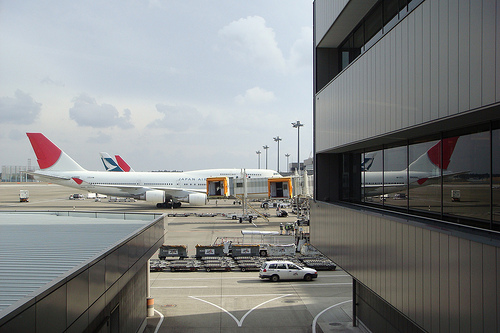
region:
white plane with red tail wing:
[22, 123, 293, 218]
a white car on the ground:
[248, 255, 323, 291]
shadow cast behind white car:
[238, 267, 273, 289]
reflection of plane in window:
[350, 148, 498, 215]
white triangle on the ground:
[187, 278, 307, 330]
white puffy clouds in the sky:
[19, 23, 294, 148]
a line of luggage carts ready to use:
[152, 242, 347, 284]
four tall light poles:
[237, 120, 314, 190]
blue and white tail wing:
[99, 146, 130, 182]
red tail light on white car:
[263, 263, 269, 273]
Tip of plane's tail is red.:
[18, 127, 63, 169]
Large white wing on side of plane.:
[66, 171, 217, 223]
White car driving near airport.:
[248, 240, 330, 321]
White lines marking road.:
[186, 270, 295, 330]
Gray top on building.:
[18, 248, 145, 318]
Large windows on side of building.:
[333, 131, 488, 193]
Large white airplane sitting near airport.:
[45, 152, 268, 207]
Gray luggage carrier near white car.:
[162, 238, 313, 258]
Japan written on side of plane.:
[169, 175, 199, 188]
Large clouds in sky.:
[72, 43, 261, 135]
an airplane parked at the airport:
[24, 130, 300, 212]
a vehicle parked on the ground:
[254, 253, 322, 286]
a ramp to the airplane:
[207, 176, 319, 204]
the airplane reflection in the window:
[349, 135, 458, 194]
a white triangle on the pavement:
[187, 288, 299, 331]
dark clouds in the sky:
[0, 3, 325, 174]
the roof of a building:
[0, 203, 170, 324]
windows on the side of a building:
[314, 112, 499, 237]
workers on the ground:
[273, 216, 299, 237]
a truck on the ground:
[13, 184, 35, 205]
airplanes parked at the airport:
[23, 28, 408, 314]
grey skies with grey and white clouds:
[57, 25, 254, 136]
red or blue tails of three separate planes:
[20, 117, 145, 197]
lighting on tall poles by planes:
[247, 111, 302, 163]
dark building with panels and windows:
[311, 5, 486, 315]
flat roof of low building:
[0, 192, 165, 327]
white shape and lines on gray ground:
[162, 271, 337, 328]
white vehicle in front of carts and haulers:
[160, 235, 310, 280]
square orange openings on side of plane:
[200, 171, 290, 201]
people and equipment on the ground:
[225, 192, 298, 238]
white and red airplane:
[25, 130, 292, 195]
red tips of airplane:
[25, 133, 135, 184]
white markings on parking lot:
[147, 273, 352, 330]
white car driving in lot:
[261, 255, 321, 283]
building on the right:
[310, 4, 495, 325]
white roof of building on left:
[0, 210, 152, 309]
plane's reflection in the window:
[354, 150, 489, 209]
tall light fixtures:
[242, 115, 314, 170]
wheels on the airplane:
[149, 197, 190, 212]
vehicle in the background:
[17, 187, 29, 201]